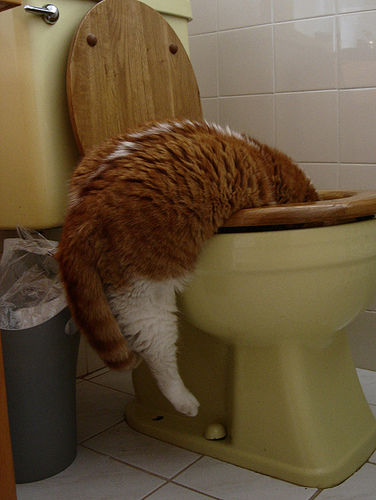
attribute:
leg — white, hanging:
[100, 241, 208, 421]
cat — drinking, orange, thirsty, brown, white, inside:
[54, 116, 327, 413]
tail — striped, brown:
[51, 203, 141, 373]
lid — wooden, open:
[63, 1, 207, 154]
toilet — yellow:
[3, 2, 366, 497]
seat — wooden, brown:
[217, 191, 375, 231]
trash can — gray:
[1, 235, 96, 483]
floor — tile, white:
[9, 377, 373, 499]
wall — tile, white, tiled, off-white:
[196, 6, 375, 191]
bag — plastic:
[5, 238, 71, 329]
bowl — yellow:
[179, 219, 375, 356]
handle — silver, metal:
[16, 1, 67, 31]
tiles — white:
[85, 440, 181, 500]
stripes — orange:
[75, 306, 123, 361]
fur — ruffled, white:
[131, 315, 180, 367]